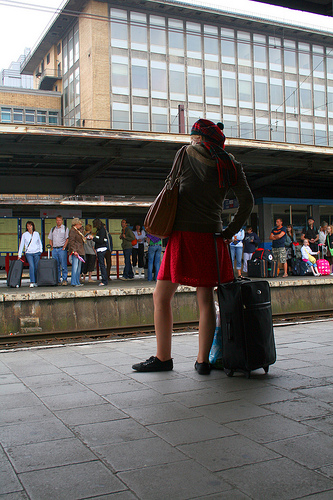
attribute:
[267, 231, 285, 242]
arms — crossed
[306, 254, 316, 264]
bag — yellow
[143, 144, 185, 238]
purse — brown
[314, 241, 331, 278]
suitcase — pink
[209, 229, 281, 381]
suitcase — black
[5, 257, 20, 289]
luggage — rolling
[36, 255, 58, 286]
luggage — rolling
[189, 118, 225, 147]
beanie — blue, green and red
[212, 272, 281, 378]
luggage — rolling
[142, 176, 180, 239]
bag — brown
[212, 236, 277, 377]
bag — rolling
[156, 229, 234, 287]
skirt — red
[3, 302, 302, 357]
tracks — brown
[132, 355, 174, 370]
shoe — black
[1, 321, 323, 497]
sidewalk — cement, tiled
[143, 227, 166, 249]
shirt — green 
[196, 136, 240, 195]
scarf — plaid